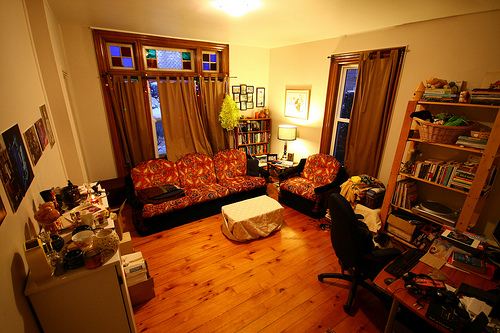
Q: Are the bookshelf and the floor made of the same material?
A: Yes, both the bookshelf and the floor are made of wood.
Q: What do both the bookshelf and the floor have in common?
A: The material, both the bookshelf and the floor are wooden.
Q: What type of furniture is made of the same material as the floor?
A: The bookshelf is made of the same material as the floor.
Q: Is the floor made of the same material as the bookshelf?
A: Yes, both the floor and the bookshelf are made of wood.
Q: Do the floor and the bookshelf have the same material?
A: Yes, both the floor and the bookshelf are made of wood.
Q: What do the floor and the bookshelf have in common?
A: The material, both the floor and the bookshelf are wooden.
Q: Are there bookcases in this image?
A: Yes, there is a bookcase.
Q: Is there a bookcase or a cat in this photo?
A: Yes, there is a bookcase.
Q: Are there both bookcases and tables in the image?
A: Yes, there are both a bookcase and a table.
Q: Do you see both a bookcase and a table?
A: Yes, there are both a bookcase and a table.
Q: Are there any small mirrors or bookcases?
A: Yes, there is a small bookcase.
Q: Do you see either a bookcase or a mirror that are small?
A: Yes, the bookcase is small.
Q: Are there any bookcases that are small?
A: Yes, there is a small bookcase.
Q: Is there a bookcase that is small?
A: Yes, there is a bookcase that is small.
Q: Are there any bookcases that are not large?
A: Yes, there is a small bookcase.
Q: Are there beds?
A: No, there are no beds.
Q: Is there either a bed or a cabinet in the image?
A: No, there are no beds or cabinets.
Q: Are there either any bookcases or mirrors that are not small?
A: No, there is a bookcase but it is small.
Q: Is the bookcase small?
A: Yes, the bookcase is small.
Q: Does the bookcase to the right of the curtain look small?
A: Yes, the bookcase is small.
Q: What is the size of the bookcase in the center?
A: The bookcase is small.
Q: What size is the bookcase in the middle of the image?
A: The bookcase is small.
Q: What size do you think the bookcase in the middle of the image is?
A: The bookcase is small.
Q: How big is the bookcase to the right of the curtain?
A: The bookcase is small.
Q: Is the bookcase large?
A: No, the bookcase is small.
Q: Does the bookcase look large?
A: No, the bookcase is small.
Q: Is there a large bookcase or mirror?
A: No, there is a bookcase but it is small.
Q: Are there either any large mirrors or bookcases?
A: No, there is a bookcase but it is small.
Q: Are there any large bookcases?
A: No, there is a bookcase but it is small.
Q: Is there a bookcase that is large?
A: No, there is a bookcase but it is small.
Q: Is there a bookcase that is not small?
A: No, there is a bookcase but it is small.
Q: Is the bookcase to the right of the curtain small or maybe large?
A: The bookcase is small.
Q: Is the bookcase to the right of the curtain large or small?
A: The bookcase is small.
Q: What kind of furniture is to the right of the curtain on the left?
A: The piece of furniture is a bookcase.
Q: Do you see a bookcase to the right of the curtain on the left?
A: Yes, there is a bookcase to the right of the curtain.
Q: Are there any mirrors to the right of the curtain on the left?
A: No, there is a bookcase to the right of the curtain.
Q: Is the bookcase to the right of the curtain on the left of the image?
A: Yes, the bookcase is to the right of the curtain.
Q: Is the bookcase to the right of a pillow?
A: No, the bookcase is to the right of the curtain.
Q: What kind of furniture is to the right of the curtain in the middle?
A: The piece of furniture is a bookcase.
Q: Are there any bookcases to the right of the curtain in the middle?
A: Yes, there is a bookcase to the right of the curtain.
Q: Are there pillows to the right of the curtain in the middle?
A: No, there is a bookcase to the right of the curtain.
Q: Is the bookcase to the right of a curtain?
A: Yes, the bookcase is to the right of a curtain.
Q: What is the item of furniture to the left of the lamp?
A: The piece of furniture is a bookcase.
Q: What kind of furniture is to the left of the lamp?
A: The piece of furniture is a bookcase.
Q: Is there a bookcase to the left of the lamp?
A: Yes, there is a bookcase to the left of the lamp.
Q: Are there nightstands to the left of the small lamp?
A: No, there is a bookcase to the left of the lamp.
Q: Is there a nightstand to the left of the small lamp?
A: No, there is a bookcase to the left of the lamp.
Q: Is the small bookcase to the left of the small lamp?
A: Yes, the bookcase is to the left of the lamp.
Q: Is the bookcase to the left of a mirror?
A: No, the bookcase is to the left of the lamp.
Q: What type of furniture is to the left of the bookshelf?
A: The piece of furniture is a bookcase.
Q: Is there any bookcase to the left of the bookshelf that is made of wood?
A: Yes, there is a bookcase to the left of the bookshelf.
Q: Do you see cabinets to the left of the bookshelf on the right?
A: No, there is a bookcase to the left of the bookshelf.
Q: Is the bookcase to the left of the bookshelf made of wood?
A: Yes, the bookcase is to the left of the bookshelf.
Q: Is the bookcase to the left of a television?
A: No, the bookcase is to the left of the bookshelf.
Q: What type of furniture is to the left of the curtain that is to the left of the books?
A: The piece of furniture is a bookcase.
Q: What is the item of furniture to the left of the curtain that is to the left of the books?
A: The piece of furniture is a bookcase.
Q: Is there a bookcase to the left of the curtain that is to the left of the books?
A: Yes, there is a bookcase to the left of the curtain.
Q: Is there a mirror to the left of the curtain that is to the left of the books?
A: No, there is a bookcase to the left of the curtain.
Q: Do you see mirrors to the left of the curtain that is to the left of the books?
A: No, there is a bookcase to the left of the curtain.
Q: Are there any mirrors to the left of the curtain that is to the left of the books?
A: No, there is a bookcase to the left of the curtain.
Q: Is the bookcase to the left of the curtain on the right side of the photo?
A: Yes, the bookcase is to the left of the curtain.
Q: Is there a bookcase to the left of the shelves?
A: Yes, there is a bookcase to the left of the shelves.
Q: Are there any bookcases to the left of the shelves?
A: Yes, there is a bookcase to the left of the shelves.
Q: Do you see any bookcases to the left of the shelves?
A: Yes, there is a bookcase to the left of the shelves.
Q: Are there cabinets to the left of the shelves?
A: No, there is a bookcase to the left of the shelves.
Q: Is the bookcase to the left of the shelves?
A: Yes, the bookcase is to the left of the shelves.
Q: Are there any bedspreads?
A: No, there are no bedspreads.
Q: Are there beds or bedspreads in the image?
A: No, there are no bedspreads or beds.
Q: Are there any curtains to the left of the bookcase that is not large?
A: Yes, there is a curtain to the left of the bookcase.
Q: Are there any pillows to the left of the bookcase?
A: No, there is a curtain to the left of the bookcase.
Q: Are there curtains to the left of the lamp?
A: Yes, there is a curtain to the left of the lamp.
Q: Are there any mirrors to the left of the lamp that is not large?
A: No, there is a curtain to the left of the lamp.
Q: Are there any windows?
A: Yes, there is a window.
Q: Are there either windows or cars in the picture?
A: Yes, there is a window.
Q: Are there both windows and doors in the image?
A: No, there is a window but no doors.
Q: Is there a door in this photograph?
A: No, there are no doors.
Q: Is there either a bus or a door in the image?
A: No, there are no doors or buses.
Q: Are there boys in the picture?
A: No, there are no boys.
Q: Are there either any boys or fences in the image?
A: No, there are no boys or fences.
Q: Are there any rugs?
A: No, there are no rugs.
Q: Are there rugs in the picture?
A: No, there are no rugs.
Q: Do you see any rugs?
A: No, there are no rugs.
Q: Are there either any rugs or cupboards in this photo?
A: No, there are no rugs or cupboards.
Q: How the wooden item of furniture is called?
A: The piece of furniture is a bookshelf.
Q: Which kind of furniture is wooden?
A: The furniture is a bookshelf.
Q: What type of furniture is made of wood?
A: The furniture is a bookshelf.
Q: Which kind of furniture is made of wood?
A: The furniture is a bookshelf.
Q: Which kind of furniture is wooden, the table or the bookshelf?
A: The bookshelf is wooden.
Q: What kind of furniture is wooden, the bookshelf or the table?
A: The bookshelf is wooden.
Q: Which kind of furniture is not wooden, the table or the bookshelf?
A: The table is not wooden.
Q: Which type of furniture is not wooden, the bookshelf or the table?
A: The table is not wooden.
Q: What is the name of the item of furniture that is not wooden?
A: The piece of furniture is a table.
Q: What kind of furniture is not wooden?
A: The furniture is a table.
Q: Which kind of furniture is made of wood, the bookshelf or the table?
A: The bookshelf is made of wood.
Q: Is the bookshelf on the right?
A: Yes, the bookshelf is on the right of the image.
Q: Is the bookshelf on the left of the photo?
A: No, the bookshelf is on the right of the image.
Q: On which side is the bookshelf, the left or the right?
A: The bookshelf is on the right of the image.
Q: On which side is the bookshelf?
A: The bookshelf is on the right of the image.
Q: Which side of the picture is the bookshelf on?
A: The bookshelf is on the right of the image.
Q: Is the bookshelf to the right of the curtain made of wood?
A: Yes, the bookshelf is made of wood.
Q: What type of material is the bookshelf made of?
A: The bookshelf is made of wood.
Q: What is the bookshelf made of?
A: The bookshelf is made of wood.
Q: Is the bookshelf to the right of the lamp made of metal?
A: No, the bookshelf is made of wood.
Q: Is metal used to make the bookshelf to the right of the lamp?
A: No, the bookshelf is made of wood.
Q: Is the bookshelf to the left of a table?
A: No, the bookshelf is to the right of a table.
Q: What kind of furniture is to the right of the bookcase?
A: The piece of furniture is a bookshelf.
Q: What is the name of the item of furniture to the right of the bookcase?
A: The piece of furniture is a bookshelf.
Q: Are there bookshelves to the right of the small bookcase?
A: Yes, there is a bookshelf to the right of the bookcase.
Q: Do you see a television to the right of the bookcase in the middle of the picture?
A: No, there is a bookshelf to the right of the bookcase.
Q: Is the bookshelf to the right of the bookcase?
A: Yes, the bookshelf is to the right of the bookcase.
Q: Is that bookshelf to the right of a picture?
A: No, the bookshelf is to the right of the bookcase.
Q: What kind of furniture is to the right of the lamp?
A: The piece of furniture is a bookshelf.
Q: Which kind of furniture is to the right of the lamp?
A: The piece of furniture is a bookshelf.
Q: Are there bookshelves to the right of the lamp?
A: Yes, there is a bookshelf to the right of the lamp.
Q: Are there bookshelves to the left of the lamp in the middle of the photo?
A: No, the bookshelf is to the right of the lamp.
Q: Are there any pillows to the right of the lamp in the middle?
A: No, there is a bookshelf to the right of the lamp.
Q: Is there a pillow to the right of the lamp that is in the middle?
A: No, there is a bookshelf to the right of the lamp.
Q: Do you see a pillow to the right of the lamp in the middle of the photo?
A: No, there is a bookshelf to the right of the lamp.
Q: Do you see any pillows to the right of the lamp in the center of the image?
A: No, there is a bookshelf to the right of the lamp.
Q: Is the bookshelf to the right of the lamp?
A: Yes, the bookshelf is to the right of the lamp.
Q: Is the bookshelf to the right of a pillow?
A: No, the bookshelf is to the right of the lamp.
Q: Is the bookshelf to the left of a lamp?
A: No, the bookshelf is to the right of a lamp.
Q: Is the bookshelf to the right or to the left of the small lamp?
A: The bookshelf is to the right of the lamp.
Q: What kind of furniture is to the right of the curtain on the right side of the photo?
A: The piece of furniture is a bookshelf.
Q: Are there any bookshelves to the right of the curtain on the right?
A: Yes, there is a bookshelf to the right of the curtain.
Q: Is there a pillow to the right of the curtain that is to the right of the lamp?
A: No, there is a bookshelf to the right of the curtain.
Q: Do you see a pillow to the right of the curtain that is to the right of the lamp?
A: No, there is a bookshelf to the right of the curtain.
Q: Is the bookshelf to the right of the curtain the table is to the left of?
A: Yes, the bookshelf is to the right of the curtain.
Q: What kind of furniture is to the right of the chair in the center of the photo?
A: The piece of furniture is a bookshelf.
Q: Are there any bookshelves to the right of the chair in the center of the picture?
A: Yes, there is a bookshelf to the right of the chair.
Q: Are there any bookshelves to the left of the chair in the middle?
A: No, the bookshelf is to the right of the chair.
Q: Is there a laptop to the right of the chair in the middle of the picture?
A: No, there is a bookshelf to the right of the chair.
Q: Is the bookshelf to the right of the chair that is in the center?
A: Yes, the bookshelf is to the right of the chair.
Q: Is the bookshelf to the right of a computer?
A: No, the bookshelf is to the right of the chair.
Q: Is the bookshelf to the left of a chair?
A: No, the bookshelf is to the right of a chair.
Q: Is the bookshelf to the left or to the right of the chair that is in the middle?
A: The bookshelf is to the right of the chair.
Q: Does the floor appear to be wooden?
A: Yes, the floor is wooden.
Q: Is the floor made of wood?
A: Yes, the floor is made of wood.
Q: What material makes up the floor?
A: The floor is made of wood.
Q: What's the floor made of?
A: The floor is made of wood.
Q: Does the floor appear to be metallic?
A: No, the floor is wooden.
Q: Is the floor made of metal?
A: No, the floor is made of wood.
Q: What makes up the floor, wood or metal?
A: The floor is made of wood.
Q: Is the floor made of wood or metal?
A: The floor is made of wood.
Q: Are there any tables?
A: Yes, there is a table.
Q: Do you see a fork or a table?
A: Yes, there is a table.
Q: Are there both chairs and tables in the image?
A: Yes, there are both a table and a chair.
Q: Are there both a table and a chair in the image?
A: Yes, there are both a table and a chair.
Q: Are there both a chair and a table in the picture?
A: Yes, there are both a table and a chair.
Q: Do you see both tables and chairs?
A: Yes, there are both a table and a chair.